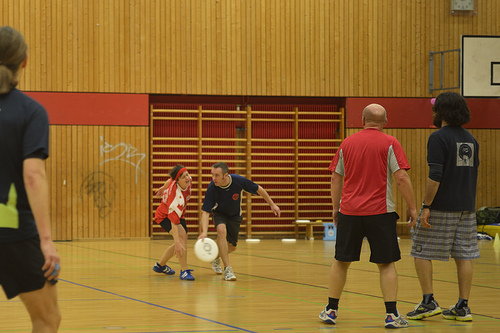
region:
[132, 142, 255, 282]
the people are playing frisbee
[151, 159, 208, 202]
the woman has red headband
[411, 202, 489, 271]
the man's shorts are striped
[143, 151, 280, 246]
the man and woman are bending over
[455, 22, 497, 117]
the basketball goal is black and white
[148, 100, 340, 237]
the structure is made of wood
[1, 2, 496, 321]
the people are in a gym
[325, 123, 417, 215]
the man's shirt is red and gray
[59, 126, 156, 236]
graffiti is on the walls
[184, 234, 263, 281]
the frisbee is white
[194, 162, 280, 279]
Man with blue shirt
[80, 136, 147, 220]
graffiti on wooden wall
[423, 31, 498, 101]
basketball hoop attached to wall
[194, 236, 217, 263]
large white plastic frisbee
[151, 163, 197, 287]
girl wearing blue sneakers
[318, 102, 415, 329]
man wearing black shorts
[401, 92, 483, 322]
man wearing plaid shorts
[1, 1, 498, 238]
light wooden paneled walls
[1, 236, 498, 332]
light waxed basketball floor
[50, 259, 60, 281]
light blue finger wrap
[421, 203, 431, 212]
A black wrist watch.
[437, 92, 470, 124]
A black cap.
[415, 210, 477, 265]
Gray and black shorts.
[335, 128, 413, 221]
Red and gray short sleeved shirt.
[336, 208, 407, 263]
Black shorts.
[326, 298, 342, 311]
Black sock.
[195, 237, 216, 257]
White frisbee in the player's right hand..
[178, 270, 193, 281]
Woman's blue tennis shoe.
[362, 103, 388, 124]
An almost bald head.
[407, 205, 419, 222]
A man's right hand.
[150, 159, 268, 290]
they are playing basketball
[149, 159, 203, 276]
he is wearing a white and red shirt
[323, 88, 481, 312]
they are watching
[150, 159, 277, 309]
they have a frisbee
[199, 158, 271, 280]
he is wearing a blue shirt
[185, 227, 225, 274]
the frisbee is white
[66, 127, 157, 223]
the grafitti is on the wall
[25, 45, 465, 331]
they are in a gym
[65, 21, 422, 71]
the wall is wood paneling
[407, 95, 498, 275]
he is wearing stripped shorts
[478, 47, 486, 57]
basket ball board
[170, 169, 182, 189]
part of a red haead gear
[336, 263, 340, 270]
left leg of a man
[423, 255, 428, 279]
left leg of a boy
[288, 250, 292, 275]
part of a wooden surface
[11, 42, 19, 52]
part of a girl's hair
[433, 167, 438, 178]
elbow of a boy